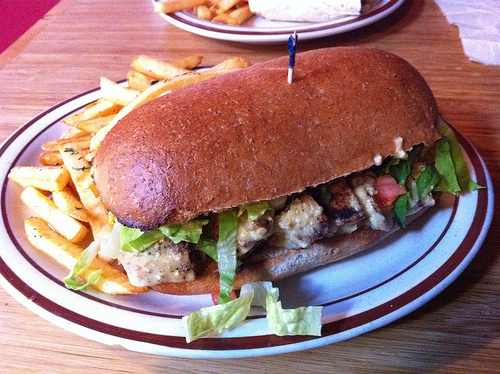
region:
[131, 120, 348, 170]
the bun is brown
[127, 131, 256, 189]
the bun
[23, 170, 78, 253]
the french frys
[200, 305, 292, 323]
lettuce on the plate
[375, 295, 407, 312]
rim of the plate is brown and white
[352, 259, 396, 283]
the plate is white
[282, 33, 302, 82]
a toothpick in the sandwhich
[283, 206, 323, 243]
meat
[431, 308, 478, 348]
a shadow on the table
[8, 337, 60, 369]
the table is wooden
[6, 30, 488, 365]
a sandwich on a plate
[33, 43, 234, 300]
french fries on the plate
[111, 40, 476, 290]
chicken sandwich with lettuce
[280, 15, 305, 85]
toothpick in the sandwich to keep it together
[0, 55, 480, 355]
white plate with brown around the edge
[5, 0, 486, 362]
plate on the wooden table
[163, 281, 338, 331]
lettuce that has fallen onto the plate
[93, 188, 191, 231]
bread is slightly burnt around the edges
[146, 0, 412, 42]
a second plate with french fries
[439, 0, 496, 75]
a napkin on the table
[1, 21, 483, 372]
sandwich on a white plate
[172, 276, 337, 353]
piece of food sitting on a white plate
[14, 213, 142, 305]
piece of food sitting on a white plate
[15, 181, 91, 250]
piece of food sitting on a white plate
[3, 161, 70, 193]
piece of food sitting on a white plate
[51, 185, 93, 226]
piece of food sitting on a white plate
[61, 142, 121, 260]
piece of food sitting on a white plate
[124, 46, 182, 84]
piece of food sitting on a white plate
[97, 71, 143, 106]
piece of food sitting on a white plate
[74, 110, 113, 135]
piece of food sitting on a white plate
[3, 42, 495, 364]
A plate full with food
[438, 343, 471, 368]
Part of the table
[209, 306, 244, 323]
Part of the lettuce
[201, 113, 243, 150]
Part of the bread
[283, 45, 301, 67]
Part of the toothpick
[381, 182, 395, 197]
Part of the tomato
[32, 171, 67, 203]
Part of the fries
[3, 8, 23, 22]
Part of the carpet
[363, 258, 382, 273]
Part of the plate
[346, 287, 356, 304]
Part of the line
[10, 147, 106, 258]
golden french fries on the plate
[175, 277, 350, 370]
green lettuce falling out of the sandwich on the plate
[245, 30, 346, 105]
white toothpick with blue paper on the end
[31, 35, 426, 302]
toasted sandwich with vegetables and french fries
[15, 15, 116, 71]
wood grain on table top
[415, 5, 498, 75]
white napkin laying on table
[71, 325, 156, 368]
chip on the rim of the dinner plate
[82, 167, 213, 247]
toasted bread on sandwich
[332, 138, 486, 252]
lettuce and tomatoes on sandwich